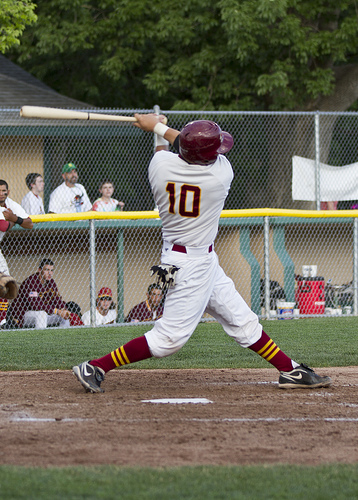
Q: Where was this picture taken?
A: A baseball field.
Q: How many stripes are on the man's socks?
A: Three.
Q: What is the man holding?
A: A bat.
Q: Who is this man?
A: A baseball player.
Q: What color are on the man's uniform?
A: White, maroon, and yellow.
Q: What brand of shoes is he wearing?
A: Nike.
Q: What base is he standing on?
A: Home.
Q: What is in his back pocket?
A: Gloves.